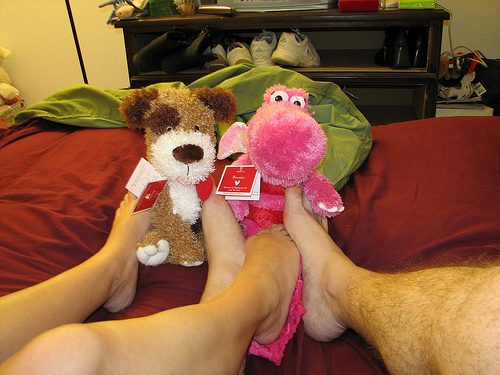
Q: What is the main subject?
A: Stuffed animals.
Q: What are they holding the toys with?
A: Feet.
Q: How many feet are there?
A: 4.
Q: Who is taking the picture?
A: Man and woman.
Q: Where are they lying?
A: On the bed.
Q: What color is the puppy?
A: Brown and white.